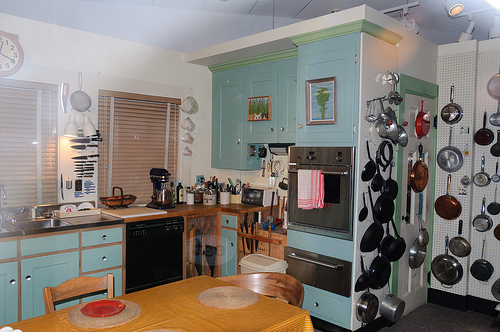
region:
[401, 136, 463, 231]
2 catercorner copper bottom skillets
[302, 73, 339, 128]
an indistinct painting of possibly a green tree with yellow flowers in a brown frame above a silvertone stove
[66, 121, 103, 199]
a large wild connection of knives affixed to the wall beside the sink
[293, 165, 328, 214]
some red+white kitchen towels hanging from the oven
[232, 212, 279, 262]
some more knives [?] hanging from a wooden drawer pull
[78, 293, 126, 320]
a solitary red plate with somewhat fluted edges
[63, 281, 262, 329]
two beigey brown woven placemats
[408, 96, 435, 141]
a red skillet with an odd white decoration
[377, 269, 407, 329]
a silvertone soup pot nearing the floor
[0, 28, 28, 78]
a cream round clock with a beige frame, time sez around 12:20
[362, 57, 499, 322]
pot and pans hanging on wall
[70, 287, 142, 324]
red plate on kitchen table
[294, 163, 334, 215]
red and white towel hanging from stove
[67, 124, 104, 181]
kitchen knives hanging on wall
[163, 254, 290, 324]
kitchen table with yellow table cloth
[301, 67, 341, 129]
art work hung on cabinet door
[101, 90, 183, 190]
light brown mini blinds covering windows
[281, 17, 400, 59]
wooden trim painted mint green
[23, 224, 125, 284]
kitchen cabinets and draws painted light blue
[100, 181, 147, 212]
basket with fruit on kitchen counter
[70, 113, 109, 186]
Shiny knives on wall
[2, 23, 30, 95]
Brown and white clock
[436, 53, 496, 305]
Shiny pans hanging on white wall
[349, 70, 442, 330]
Whiny pots and pans hanging on wall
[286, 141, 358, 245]
Silver oven with red and white towel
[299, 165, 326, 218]
Red and white towel hanging from oven handle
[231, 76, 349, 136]
Pictures hanging on blue wall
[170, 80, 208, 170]
Kitchen utensils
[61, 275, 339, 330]
Gold table cloth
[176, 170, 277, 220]
Many utensils in containers on counter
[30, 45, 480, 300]
Picture is taken in kitchen.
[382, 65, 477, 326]
Pans are hanging in wall.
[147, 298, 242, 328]
Table is brown color.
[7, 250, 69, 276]
Cupboard is blue color.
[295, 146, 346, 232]
Oven is grey color.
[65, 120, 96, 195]
Knifes are hanging in wall.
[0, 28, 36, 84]
One clock is seen.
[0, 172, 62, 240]
Sink is silver color.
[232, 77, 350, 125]
Pictures are attached to the wall.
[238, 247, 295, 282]
Trash is white color.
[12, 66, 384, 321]
small kitchen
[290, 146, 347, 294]
stainless steel oven and broiler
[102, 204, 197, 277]
black front dishwasher in kitchen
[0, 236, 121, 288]
blue cabinets under sink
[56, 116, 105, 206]
kitchen knives stuck to wall by magnets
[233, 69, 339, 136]
framed artwork n blue kitchen cabinets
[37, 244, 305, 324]
two chairs do not match at table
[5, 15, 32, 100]
clock with white face and wooden trim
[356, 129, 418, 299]
black frying pans hung on a wall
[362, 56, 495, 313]
wall with assorted kitchen pans hanging up